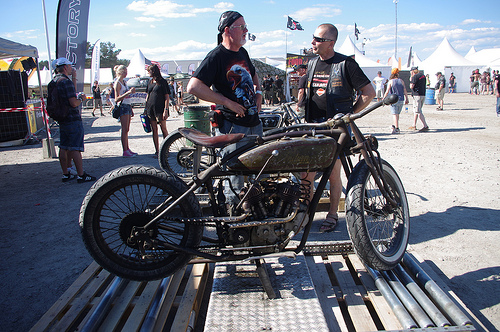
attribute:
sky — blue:
[0, 3, 496, 63]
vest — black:
[302, 56, 349, 113]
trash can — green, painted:
[179, 103, 217, 138]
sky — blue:
[414, 1, 448, 11]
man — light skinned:
[213, 6, 261, 56]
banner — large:
[51, 2, 88, 102]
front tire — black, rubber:
[341, 152, 413, 272]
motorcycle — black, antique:
[78, 78, 409, 280]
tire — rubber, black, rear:
[76, 167, 204, 282]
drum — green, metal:
[184, 105, 214, 158]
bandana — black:
[216, 8, 245, 34]